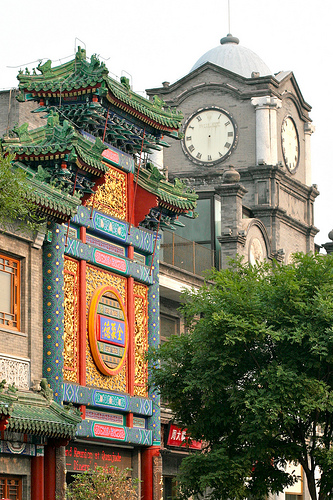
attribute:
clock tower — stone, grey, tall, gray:
[143, 30, 311, 277]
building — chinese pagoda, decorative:
[0, 45, 199, 499]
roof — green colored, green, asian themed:
[1, 44, 199, 230]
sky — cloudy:
[3, 1, 333, 256]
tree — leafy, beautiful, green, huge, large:
[143, 247, 333, 498]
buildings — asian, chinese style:
[0, 30, 333, 498]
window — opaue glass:
[1, 252, 23, 330]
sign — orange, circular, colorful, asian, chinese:
[86, 281, 130, 377]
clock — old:
[179, 105, 237, 165]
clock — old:
[281, 110, 301, 173]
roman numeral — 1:
[215, 112, 223, 119]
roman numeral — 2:
[221, 118, 232, 128]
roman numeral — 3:
[225, 129, 234, 139]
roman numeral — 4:
[223, 140, 233, 149]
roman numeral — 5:
[217, 151, 224, 157]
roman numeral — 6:
[204, 153, 213, 160]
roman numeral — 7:
[193, 151, 201, 159]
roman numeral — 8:
[187, 145, 198, 157]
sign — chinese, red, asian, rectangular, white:
[166, 422, 205, 452]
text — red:
[64, 446, 124, 471]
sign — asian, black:
[66, 442, 133, 476]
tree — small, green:
[64, 463, 138, 499]